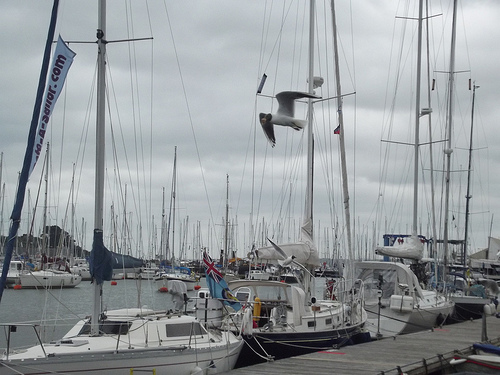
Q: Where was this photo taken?
A: A shipyard.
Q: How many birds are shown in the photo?
A: One.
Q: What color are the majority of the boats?
A: White.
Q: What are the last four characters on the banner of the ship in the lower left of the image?
A: .com.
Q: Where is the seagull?
A: In the sky.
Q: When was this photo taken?
A: Day time.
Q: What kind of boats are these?
A: Sailboats.